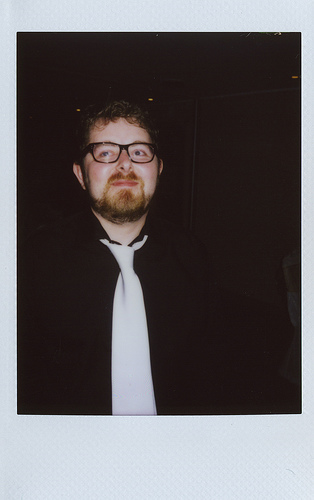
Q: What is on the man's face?
A: Glasses.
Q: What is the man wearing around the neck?
A: A necktie.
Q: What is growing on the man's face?
A: A beard.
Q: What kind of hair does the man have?
A: Curly.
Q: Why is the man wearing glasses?
A: To see better.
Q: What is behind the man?
A: Darkness.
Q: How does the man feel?
A: Happy.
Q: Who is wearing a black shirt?
A: The man.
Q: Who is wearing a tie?
A: The man.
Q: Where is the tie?
A: On the man.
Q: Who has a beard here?
A: The man.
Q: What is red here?
A: Beard.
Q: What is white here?
A: The tie.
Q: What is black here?
A: The shirt.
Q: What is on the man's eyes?
A: Glasses.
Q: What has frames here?
A: Glasses.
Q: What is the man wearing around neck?
A: A tie.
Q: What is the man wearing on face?
A: Glasses.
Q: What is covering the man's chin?
A: A beard.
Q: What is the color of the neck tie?
A: White.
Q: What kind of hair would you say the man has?
A: Short and curley.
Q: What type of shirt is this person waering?
A: Black.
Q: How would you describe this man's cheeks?
A: Chubby.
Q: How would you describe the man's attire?
A: Formal.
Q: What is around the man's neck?
A: Tie.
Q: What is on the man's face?
A: Glasses.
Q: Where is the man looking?
A: To the left.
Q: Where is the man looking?
A: Left.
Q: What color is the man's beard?
A: Brown.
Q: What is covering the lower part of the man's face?
A: Beard.